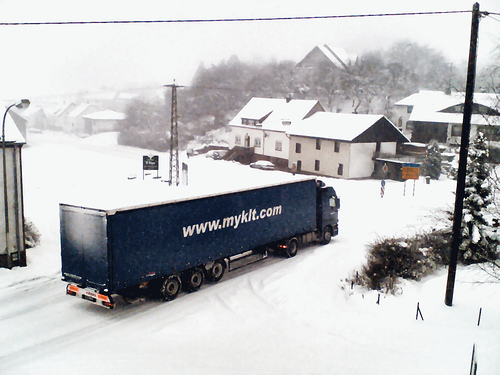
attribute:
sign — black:
[137, 150, 162, 181]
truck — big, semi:
[66, 153, 367, 320]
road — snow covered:
[13, 303, 105, 356]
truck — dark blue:
[79, 183, 355, 303]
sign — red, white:
[372, 153, 421, 204]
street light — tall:
[6, 93, 25, 263]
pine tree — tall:
[450, 125, 481, 251]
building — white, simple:
[286, 110, 379, 174]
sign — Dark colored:
[139, 150, 159, 177]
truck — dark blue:
[68, 184, 335, 294]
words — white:
[174, 202, 291, 232]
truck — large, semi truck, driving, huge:
[47, 170, 347, 323]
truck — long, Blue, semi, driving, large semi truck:
[57, 154, 348, 315]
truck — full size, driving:
[44, 180, 355, 332]